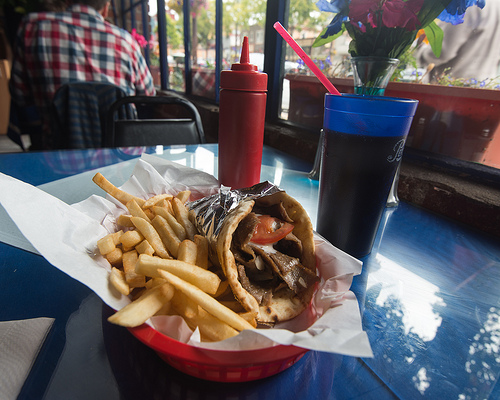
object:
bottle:
[214, 32, 271, 191]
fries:
[84, 165, 264, 343]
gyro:
[185, 181, 320, 329]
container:
[100, 184, 350, 387]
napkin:
[0, 314, 56, 397]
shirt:
[5, 5, 156, 148]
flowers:
[307, 2, 488, 64]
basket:
[89, 176, 349, 391]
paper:
[0, 146, 381, 369]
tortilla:
[209, 186, 319, 327]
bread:
[213, 187, 319, 322]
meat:
[229, 198, 319, 302]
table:
[5, 144, 495, 398]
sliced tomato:
[250, 216, 291, 242]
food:
[82, 169, 330, 356]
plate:
[100, 304, 316, 398]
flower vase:
[351, 57, 398, 92]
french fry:
[153, 266, 257, 332]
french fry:
[127, 214, 172, 258]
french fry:
[89, 168, 145, 205]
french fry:
[167, 193, 196, 238]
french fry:
[147, 211, 186, 252]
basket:
[128, 321, 310, 383]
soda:
[315, 124, 406, 259]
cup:
[315, 90, 418, 260]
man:
[8, 1, 157, 151]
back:
[22, 11, 134, 151]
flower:
[315, 0, 351, 29]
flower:
[345, 0, 381, 32]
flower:
[379, 1, 425, 34]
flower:
[439, 0, 484, 25]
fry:
[131, 250, 221, 294]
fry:
[153, 265, 253, 332]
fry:
[103, 279, 175, 329]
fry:
[91, 170, 145, 206]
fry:
[169, 195, 197, 238]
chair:
[101, 92, 207, 146]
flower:
[349, 0, 381, 33]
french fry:
[131, 249, 221, 295]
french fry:
[104, 278, 174, 329]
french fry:
[109, 263, 131, 295]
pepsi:
[315, 125, 407, 259]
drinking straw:
[271, 20, 371, 134]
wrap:
[189, 179, 319, 325]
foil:
[185, 178, 285, 265]